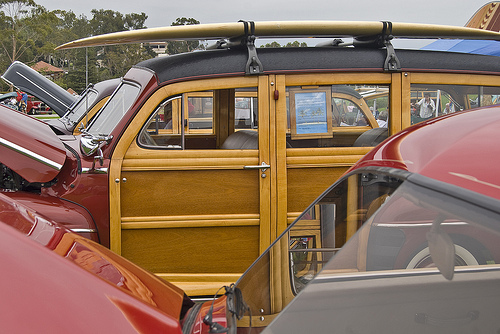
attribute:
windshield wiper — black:
[206, 282, 236, 330]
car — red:
[0, 103, 497, 332]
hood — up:
[52, 233, 189, 333]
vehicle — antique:
[0, 32, 497, 311]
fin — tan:
[449, 1, 498, 38]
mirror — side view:
[80, 135, 104, 160]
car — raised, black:
[3, 63, 68, 118]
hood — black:
[5, 64, 72, 119]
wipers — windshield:
[205, 282, 233, 331]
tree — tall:
[3, 5, 32, 60]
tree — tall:
[94, 7, 139, 72]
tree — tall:
[164, 17, 209, 46]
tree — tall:
[73, 50, 99, 98]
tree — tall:
[129, 41, 154, 59]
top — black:
[134, 43, 498, 81]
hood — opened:
[6, 111, 79, 191]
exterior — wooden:
[95, 78, 484, 282]